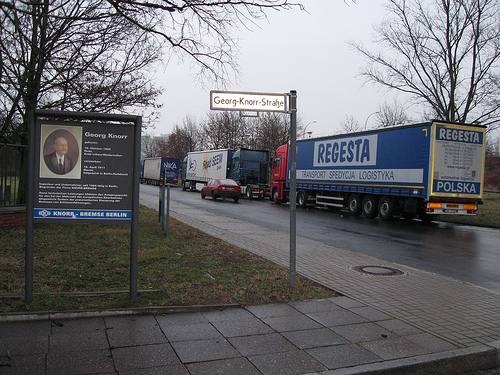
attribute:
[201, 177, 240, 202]
car — red, small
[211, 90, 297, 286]
sign — white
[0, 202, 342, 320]
grass — brown, green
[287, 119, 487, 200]
trailer — white, blue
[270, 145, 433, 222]
semi — red, blue, polish, white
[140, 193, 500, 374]
sidewalk — wet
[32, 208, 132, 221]
sign — blue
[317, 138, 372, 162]
lettering — blue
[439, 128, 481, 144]
lettering — white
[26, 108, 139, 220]
sign — brown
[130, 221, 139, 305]
pole — metal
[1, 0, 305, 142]
tree — leafless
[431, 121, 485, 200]
door edge — yellow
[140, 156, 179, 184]
semi — blue